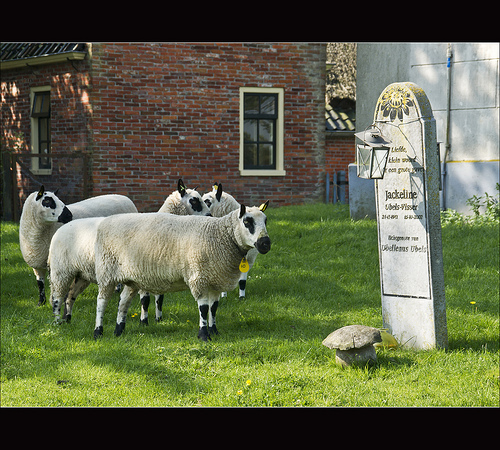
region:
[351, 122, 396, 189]
Light on top of a headstone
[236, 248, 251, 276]
yellow tag on the sheep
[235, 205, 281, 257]
sheep with black eyes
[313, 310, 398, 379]
giant mushroom in the grass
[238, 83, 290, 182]
Window frame on a brick wall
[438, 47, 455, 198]
Electric pole on a building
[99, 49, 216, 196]
brick on the face of a building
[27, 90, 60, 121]
window slightly ajar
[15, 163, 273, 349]
group of sheep standing in the grass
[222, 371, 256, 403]
Yellow flower in the grass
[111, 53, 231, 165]
A building made of brick.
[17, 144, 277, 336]
Sheep wander about the common.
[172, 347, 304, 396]
Bright green grass on a warm day.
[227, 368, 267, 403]
Two weeds growing in the grass.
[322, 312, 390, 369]
A giant mushroom grows strong.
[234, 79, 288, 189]
Large window in the house.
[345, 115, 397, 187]
A lamp hanging from the stone.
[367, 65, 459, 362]
Large grey stone in the grass.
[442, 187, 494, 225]
Small bushes next to the building.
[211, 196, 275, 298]
The sheep is wearing a yellow tag.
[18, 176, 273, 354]
Sheep in a grassy area.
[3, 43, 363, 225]
Brick building in the background.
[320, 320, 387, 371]
Small toadstool type by headstone.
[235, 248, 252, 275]
Identification tag on the animal.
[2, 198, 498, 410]
Large grassy area by buildings.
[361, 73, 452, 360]
Tall headstone sticking out of ground.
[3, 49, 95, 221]
Shadows of trees on building.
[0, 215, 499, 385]
Shadows on the grassy area.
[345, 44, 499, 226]
Large cement type building.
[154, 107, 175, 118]
black brick on side of wall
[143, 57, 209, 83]
section of red bricks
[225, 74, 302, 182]
white frame on side of building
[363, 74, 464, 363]
tall gray grave stone in the grass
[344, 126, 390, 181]
small gray lantern on grave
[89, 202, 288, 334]
white sheep on the grass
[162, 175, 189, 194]
black ears on the sheep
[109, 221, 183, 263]
white wool on sheep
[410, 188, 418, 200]
black letter on stone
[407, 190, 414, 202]
black letter on stone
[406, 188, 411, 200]
black letter on stone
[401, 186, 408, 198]
black letter on stone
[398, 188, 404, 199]
black letter on stone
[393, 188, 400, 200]
black letter on stone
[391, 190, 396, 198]
black letter on stone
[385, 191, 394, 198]
black letter on stone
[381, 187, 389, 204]
black letter on stone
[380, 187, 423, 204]
black letters on stone